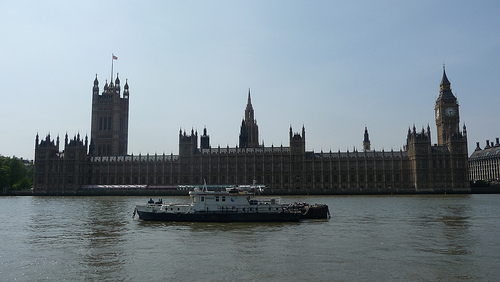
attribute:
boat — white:
[134, 180, 331, 223]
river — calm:
[9, 204, 91, 271]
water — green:
[2, 195, 499, 280]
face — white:
[444, 108, 458, 115]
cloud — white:
[174, 47, 218, 92]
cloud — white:
[2, 127, 26, 149]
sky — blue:
[1, 0, 498, 160]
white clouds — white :
[19, 16, 130, 54]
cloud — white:
[226, 17, 302, 77]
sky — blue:
[1, 3, 497, 143]